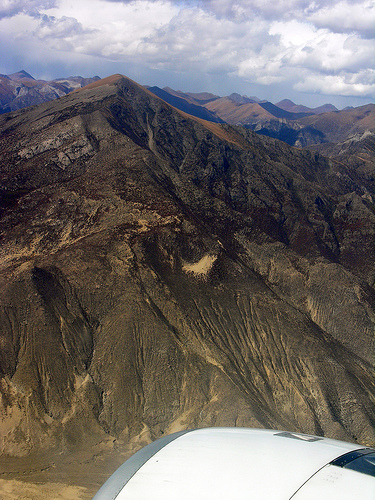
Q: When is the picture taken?
A: Daytime.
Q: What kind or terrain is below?
A: Maountains.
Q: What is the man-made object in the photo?
A: Jet engine.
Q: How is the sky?
A: Cloudy.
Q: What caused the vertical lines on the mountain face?
A: Water.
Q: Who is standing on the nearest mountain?
A: No one.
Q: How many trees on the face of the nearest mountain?
A: None.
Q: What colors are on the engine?
A: White, blue and silver.